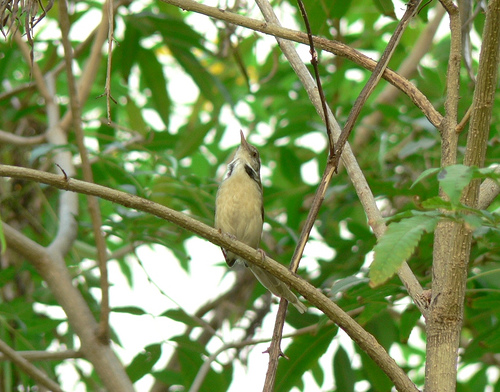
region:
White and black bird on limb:
[203, 114, 278, 289]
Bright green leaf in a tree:
[277, 316, 322, 388]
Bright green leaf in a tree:
[324, 335, 375, 389]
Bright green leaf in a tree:
[360, 174, 435, 273]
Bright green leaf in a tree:
[128, 94, 181, 151]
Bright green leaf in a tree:
[151, 11, 233, 91]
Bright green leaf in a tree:
[162, 326, 222, 388]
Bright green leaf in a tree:
[249, 303, 348, 388]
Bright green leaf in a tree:
[330, 309, 397, 384]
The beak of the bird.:
[237, 130, 248, 144]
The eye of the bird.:
[252, 151, 257, 158]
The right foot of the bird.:
[255, 245, 266, 261]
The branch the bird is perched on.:
[5, 160, 373, 351]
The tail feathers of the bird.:
[253, 259, 305, 311]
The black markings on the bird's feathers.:
[225, 158, 254, 183]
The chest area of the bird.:
[220, 165, 259, 235]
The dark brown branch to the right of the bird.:
[288, 26, 410, 275]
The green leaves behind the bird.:
[5, 12, 440, 252]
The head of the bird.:
[228, 127, 262, 170]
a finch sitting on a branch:
[204, 118, 270, 264]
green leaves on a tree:
[92, 227, 229, 361]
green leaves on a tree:
[385, 150, 484, 268]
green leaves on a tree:
[139, 13, 249, 115]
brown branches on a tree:
[420, 102, 497, 153]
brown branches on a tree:
[272, 24, 377, 118]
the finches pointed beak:
[232, 120, 251, 152]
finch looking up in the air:
[206, 125, 286, 277]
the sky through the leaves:
[148, 250, 187, 305]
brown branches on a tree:
[4, 5, 48, 44]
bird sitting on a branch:
[205, 123, 290, 299]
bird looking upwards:
[206, 118, 268, 274]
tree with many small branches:
[14, 25, 468, 370]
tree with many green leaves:
[16, 31, 477, 364]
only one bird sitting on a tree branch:
[35, 18, 471, 360]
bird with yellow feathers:
[205, 111, 312, 329]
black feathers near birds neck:
[202, 155, 274, 195]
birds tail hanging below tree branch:
[240, 243, 312, 313]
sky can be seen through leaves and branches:
[21, 23, 479, 368]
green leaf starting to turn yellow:
[365, 218, 432, 293]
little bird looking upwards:
[196, 100, 286, 292]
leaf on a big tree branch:
[355, 186, 430, 303]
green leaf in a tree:
[123, 37, 193, 126]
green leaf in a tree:
[215, 33, 262, 115]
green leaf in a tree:
[3, 291, 58, 333]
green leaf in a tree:
[273, 103, 307, 168]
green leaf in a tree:
[167, 325, 199, 374]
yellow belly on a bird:
[224, 180, 253, 235]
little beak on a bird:
[237, 126, 251, 149]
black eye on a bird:
[251, 149, 261, 158]